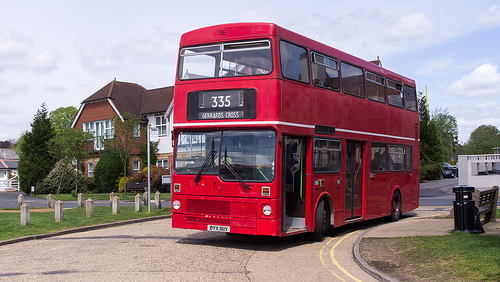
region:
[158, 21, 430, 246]
bus on the road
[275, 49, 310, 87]
window on the bus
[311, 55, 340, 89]
window on the bus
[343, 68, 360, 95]
window on the bus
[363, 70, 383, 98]
window on the bus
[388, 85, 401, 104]
window on the bus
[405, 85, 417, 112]
window on the bus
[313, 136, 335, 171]
window on the bus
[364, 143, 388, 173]
window on the bus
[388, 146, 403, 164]
window on the bus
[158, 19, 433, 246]
a double-decker bus on the road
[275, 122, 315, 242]
door of double-decker is open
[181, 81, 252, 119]
number in front the bus is 335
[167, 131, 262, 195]
two wipes over the windshield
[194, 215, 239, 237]
a white plate on the bumper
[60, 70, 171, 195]
a house of two floors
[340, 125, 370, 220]
middle door of double-decker bus is closed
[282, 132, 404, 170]
people inside the bus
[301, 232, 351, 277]
two yellow lines on right side of bus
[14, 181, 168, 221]
a fence on left side of road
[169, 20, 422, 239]
a red double decker bus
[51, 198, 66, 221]
a short concrete post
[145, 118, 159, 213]
a metal light pole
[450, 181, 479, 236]
a black trash receptacle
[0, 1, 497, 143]
a cloudy pale blue sky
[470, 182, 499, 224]
a bench next to a bus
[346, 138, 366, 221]
a double door on a bus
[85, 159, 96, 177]
a window in a building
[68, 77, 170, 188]
a white and red brick house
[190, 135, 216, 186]
a windshield wiper on a bus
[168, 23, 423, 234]
the bus is red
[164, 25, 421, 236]
the bus has two levels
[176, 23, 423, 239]
the bus has a number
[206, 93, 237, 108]
the numbers are white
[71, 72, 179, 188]
the house is brown and white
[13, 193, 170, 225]
the posts are grey and white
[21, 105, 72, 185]
the trees are tall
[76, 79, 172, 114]
the roof is dark brown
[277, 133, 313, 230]
the door is open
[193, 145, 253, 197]
the windshield wipers are up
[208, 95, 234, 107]
white number print on a bus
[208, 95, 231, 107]
335 number print on a bus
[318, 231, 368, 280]
double curve lines on a road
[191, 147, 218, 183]
a bus's winshield wiper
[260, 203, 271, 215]
round white light on a bus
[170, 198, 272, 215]
two round white lights on a bus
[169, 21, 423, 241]
red double decker bus on a road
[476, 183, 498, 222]
empty black bench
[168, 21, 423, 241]
double decker bus on a road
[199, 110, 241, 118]
small text print on a bus